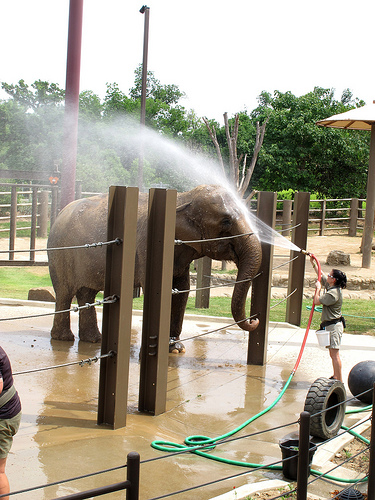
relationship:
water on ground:
[67, 115, 301, 294] [170, 373, 268, 439]